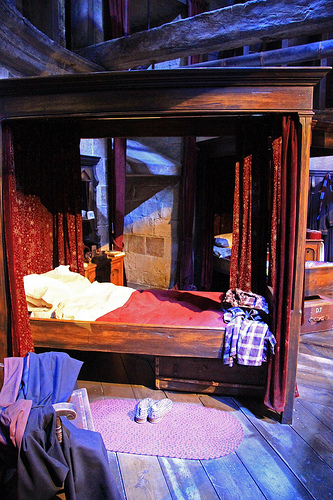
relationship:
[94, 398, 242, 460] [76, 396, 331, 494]
rug on floor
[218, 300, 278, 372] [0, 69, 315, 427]
shirt on bed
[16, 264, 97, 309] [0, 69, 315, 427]
pillow on bed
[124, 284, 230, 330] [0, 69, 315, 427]
red blanket on bed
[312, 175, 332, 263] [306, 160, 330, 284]
clothes hanging in closet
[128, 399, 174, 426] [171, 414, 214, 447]
shoes on rug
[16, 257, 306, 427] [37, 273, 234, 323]
bed has sheet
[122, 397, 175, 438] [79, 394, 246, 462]
shoes on mat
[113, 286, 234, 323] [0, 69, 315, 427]
sheet on bed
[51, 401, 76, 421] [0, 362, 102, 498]
arm of chair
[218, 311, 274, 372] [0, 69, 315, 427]
shirt on bed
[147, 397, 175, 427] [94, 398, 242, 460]
shoes on rug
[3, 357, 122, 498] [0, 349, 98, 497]
clothes laying on chair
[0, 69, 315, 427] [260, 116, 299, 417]
bed with curtain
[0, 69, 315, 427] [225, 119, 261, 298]
bed with curtain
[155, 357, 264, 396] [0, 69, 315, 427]
trunk under bed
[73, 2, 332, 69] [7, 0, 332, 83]
beam on ceiling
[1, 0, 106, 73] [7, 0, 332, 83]
beam on ceiling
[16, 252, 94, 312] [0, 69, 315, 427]
pillow on bed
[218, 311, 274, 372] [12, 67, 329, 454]
shirt on bed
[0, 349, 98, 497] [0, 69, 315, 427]
chair near bed